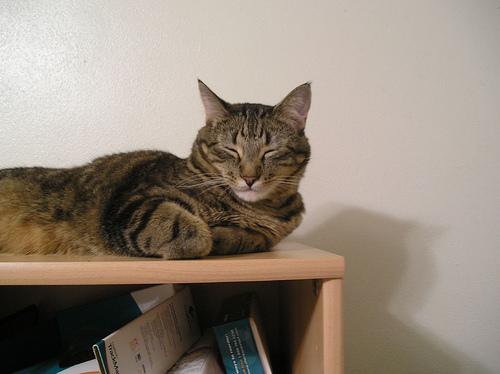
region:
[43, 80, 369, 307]
the cat is sleeping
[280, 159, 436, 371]
a shadow on the wall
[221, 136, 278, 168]
The cat's eyes are closed.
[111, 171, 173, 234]
The cat is stripped.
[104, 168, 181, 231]
The cat is brown and black.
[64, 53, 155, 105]
The wall in the background is white.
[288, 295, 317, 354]
The bookcase is made from wood.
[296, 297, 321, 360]
The bookcase is light in color.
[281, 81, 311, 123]
The cat's ear is pink in the inside.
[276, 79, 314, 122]
The cats ear is hairy in the inside.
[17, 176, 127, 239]
The cats body has fur.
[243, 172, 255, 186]
The cats nose is pink.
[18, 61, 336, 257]
Cat sleeping on a shelf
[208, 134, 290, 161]
Closed eyes of a cat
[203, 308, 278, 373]
Blue box on shelf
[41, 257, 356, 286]
Wooden shelf under cat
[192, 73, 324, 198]
Gray tabby cat on shelf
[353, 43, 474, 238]
Beige wall behind cat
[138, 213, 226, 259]
paws curled under on cat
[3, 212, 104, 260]
Fat belly of cat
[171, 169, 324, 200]
White whiskers on cat face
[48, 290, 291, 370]
books on book shelf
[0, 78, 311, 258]
striped cat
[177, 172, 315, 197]
cat whiskers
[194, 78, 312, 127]
cat ears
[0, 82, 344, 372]
striped cat lying on bookcase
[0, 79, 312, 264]
tabby cat with eyes closed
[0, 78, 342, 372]
cat relaxing on bookcase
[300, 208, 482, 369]
shadow of cat on bookcase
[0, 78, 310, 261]
striped cat with curled front paws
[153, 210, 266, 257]
striped cat paws curled under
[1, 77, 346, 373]
contented cat lounging on bookcase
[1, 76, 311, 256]
Cat is sleeping on shelf.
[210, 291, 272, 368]
Box on the shelf.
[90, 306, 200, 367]
Pamphlet on the shelf.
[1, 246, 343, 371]
Bookshelf under the cat.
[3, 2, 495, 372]
White wall in the background.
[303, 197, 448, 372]
Shadow of cat on the wall.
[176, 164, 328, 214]
White whiskers on the cat.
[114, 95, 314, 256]
Black stripes on the cat.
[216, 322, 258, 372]
Words on the side of the box.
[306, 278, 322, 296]
Silver metal bracket in the shelf.